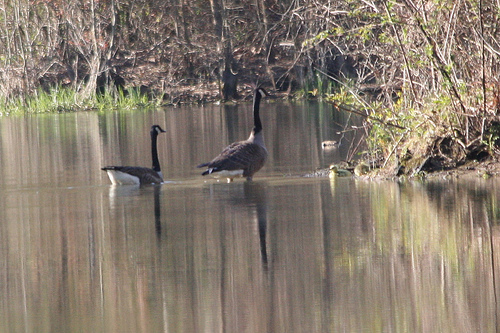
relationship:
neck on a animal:
[148, 129, 163, 173] [197, 85, 277, 182]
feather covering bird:
[102, 166, 118, 172] [102, 114, 170, 190]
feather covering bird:
[142, 172, 159, 181] [102, 114, 170, 190]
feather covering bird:
[123, 169, 138, 176] [102, 114, 170, 190]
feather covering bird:
[140, 164, 152, 169] [102, 114, 170, 190]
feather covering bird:
[150, 169, 159, 177] [102, 114, 170, 190]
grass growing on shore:
[17, 82, 139, 115] [20, 72, 480, 184]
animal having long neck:
[101, 124, 169, 185] [252, 90, 265, 134]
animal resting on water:
[101, 124, 169, 185] [6, 107, 493, 327]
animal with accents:
[101, 120, 175, 188] [108, 169, 140, 189]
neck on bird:
[250, 99, 263, 136] [196, 85, 271, 183]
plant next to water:
[291, 6, 498, 194] [249, 205, 324, 245]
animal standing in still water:
[202, 83, 277, 188] [0, 95, 500, 332]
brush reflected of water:
[279, 10, 491, 177] [6, 107, 493, 327]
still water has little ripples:
[24, 197, 217, 304] [165, 172, 227, 197]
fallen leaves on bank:
[128, 62, 158, 84] [61, 60, 353, 109]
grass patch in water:
[17, 72, 171, 107] [6, 107, 493, 327]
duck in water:
[325, 160, 356, 182] [60, 186, 418, 271]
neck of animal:
[250, 97, 263, 143] [101, 124, 169, 185]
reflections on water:
[57, 189, 373, 279] [323, 207, 436, 243]